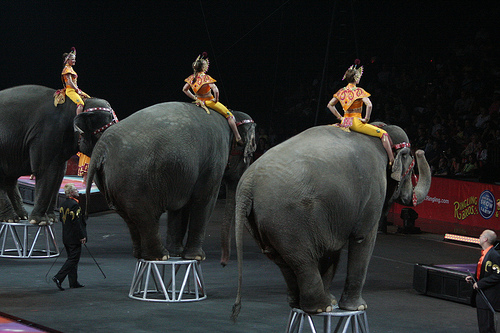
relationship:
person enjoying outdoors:
[326, 65, 378, 134] [1, 5, 496, 325]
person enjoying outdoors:
[188, 48, 239, 128] [1, 5, 496, 325]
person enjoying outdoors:
[61, 48, 82, 112] [1, 5, 496, 325]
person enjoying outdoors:
[50, 178, 85, 288] [1, 5, 496, 325]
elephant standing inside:
[245, 116, 429, 305] [253, 283, 449, 326]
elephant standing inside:
[5, 85, 116, 203] [3, 212, 109, 282]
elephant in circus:
[229, 120, 433, 325] [6, 5, 495, 320]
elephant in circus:
[86, 106, 253, 247] [6, 5, 495, 320]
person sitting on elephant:
[326, 59, 395, 166] [229, 120, 433, 325]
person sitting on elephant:
[182, 51, 247, 145] [86, 106, 253, 247]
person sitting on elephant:
[53, 47, 91, 132] [2, 89, 112, 208]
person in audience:
[452, 122, 469, 150] [376, 63, 496, 180]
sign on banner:
[452, 189, 499, 220] [391, 177, 499, 231]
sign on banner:
[452, 189, 499, 220] [388, 175, 499, 235]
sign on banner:
[452, 189, 499, 223] [384, 170, 499, 238]